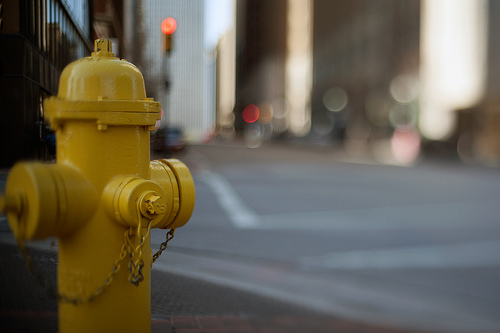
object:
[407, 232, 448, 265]
part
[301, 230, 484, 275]
line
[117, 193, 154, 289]
chain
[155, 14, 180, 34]
light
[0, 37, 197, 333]
fire hydrant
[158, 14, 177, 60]
traffic light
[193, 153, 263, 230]
line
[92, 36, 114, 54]
top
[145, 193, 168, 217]
bolt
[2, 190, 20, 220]
bolt